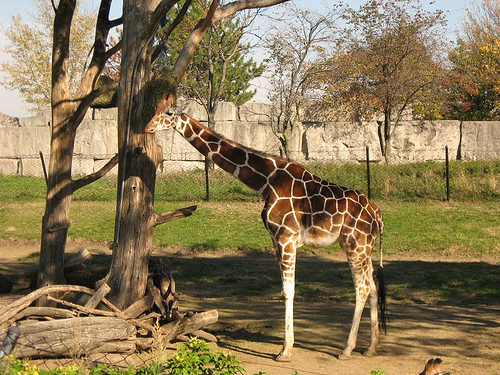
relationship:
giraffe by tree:
[144, 90, 388, 362] [154, 0, 259, 100]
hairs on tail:
[374, 266, 387, 335] [375, 233, 391, 337]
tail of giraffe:
[375, 233, 391, 337] [139, 85, 386, 366]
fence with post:
[4, 143, 496, 203] [442, 145, 451, 201]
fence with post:
[4, 143, 496, 203] [364, 145, 373, 200]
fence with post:
[4, 143, 496, 203] [201, 155, 213, 202]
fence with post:
[4, 143, 496, 203] [37, 150, 47, 182]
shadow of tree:
[407, 234, 492, 367] [37, 0, 288, 329]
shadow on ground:
[407, 234, 492, 367] [2, 169, 495, 372]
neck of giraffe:
[179, 118, 264, 190] [139, 85, 386, 366]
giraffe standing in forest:
[139, 85, 386, 366] [0, 0, 498, 172]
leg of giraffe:
[270, 242, 296, 364] [106, 76, 420, 363]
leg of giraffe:
[336, 241, 378, 358] [106, 76, 420, 363]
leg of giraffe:
[341, 242, 382, 361] [139, 78, 456, 373]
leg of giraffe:
[274, 242, 296, 348] [139, 78, 456, 373]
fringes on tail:
[376, 265, 385, 317] [375, 233, 395, 301]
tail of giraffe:
[375, 233, 395, 301] [256, 162, 331, 211]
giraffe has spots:
[144, 90, 388, 362] [248, 158, 380, 248]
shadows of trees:
[3, 233, 498, 366] [18, 2, 335, 362]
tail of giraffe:
[375, 233, 391, 337] [139, 88, 420, 367]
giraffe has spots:
[144, 90, 388, 362] [259, 156, 378, 256]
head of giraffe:
[142, 87, 188, 135] [156, 82, 392, 364]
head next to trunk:
[142, 87, 188, 135] [102, 2, 160, 300]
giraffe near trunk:
[144, 90, 388, 362] [120, 15, 195, 329]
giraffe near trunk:
[144, 90, 388, 362] [30, 12, 92, 322]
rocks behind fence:
[1, 108, 498, 183] [4, 143, 496, 203]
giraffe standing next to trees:
[139, 85, 386, 366] [38, 0, 282, 326]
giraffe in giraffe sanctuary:
[139, 85, 386, 366] [1, 94, 498, 373]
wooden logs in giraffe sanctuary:
[9, 277, 187, 364] [1, 94, 498, 373]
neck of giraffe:
[179, 118, 264, 190] [144, 90, 388, 362]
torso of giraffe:
[261, 154, 381, 257] [144, 90, 388, 362]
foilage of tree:
[309, 3, 441, 128] [288, 15, 441, 205]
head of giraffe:
[141, 87, 189, 138] [144, 90, 388, 362]